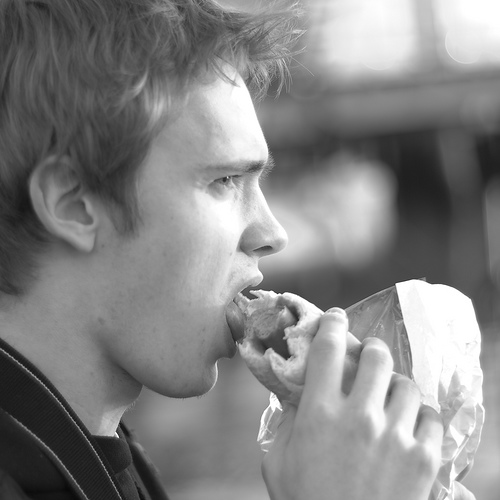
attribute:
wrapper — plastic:
[344, 259, 498, 484]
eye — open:
[208, 169, 250, 194]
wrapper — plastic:
[365, 275, 489, 366]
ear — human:
[23, 148, 100, 255]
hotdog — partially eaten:
[225, 282, 327, 410]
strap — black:
[12, 365, 148, 496]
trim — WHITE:
[4, 344, 44, 387]